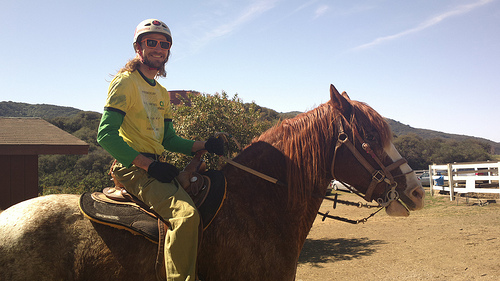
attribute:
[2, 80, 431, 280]
horse — red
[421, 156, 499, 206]
fence — white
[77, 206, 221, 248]
blanket — black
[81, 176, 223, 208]
saddle — brown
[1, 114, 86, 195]
building — brown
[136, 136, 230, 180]
gloves — black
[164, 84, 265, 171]
bush — green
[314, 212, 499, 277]
ground — dirty